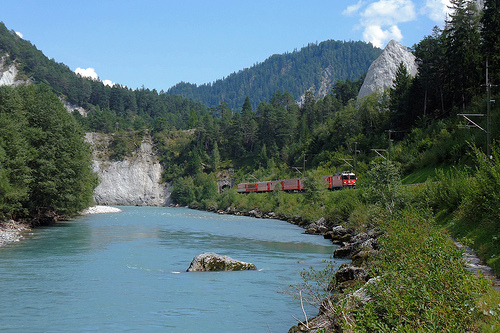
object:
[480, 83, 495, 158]
poles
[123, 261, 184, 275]
waves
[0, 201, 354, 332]
lake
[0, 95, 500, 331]
valley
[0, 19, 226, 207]
range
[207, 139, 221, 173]
trees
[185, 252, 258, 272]
rock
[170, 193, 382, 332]
shore line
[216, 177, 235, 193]
tunnel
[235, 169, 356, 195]
train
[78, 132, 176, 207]
wall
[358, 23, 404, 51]
clouds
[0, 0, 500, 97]
sky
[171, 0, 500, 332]
forest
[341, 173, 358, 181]
windshield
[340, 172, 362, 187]
train front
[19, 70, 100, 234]
evergreen tree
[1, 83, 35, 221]
evergreen tree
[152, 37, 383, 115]
mountain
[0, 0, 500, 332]
background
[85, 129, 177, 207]
cliff face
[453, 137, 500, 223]
bushes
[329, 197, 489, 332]
row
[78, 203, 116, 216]
hill ground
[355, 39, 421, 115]
hill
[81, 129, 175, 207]
cliff